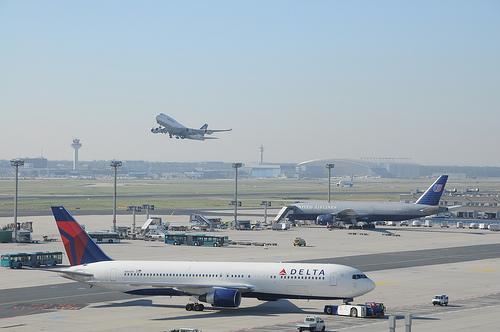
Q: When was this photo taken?
A: Daytime.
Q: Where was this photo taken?
A: An airport runway.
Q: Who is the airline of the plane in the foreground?
A: Delta.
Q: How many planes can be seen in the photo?
A: Four.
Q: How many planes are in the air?
A: One.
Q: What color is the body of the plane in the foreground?
A: White.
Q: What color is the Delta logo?
A: Red.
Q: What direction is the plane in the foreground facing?
A: Right.